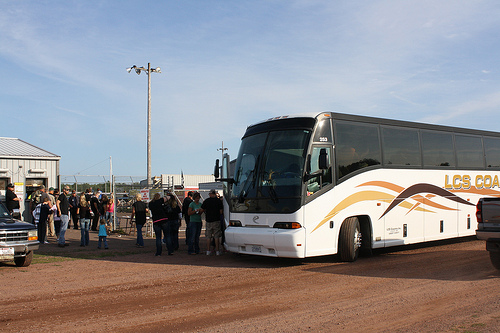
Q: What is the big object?
A: Travel bus.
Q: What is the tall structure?
A: Light post.